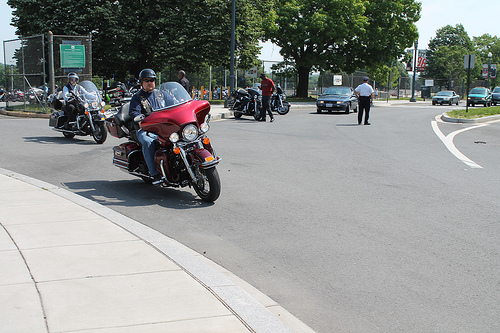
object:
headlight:
[181, 124, 199, 141]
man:
[61, 69, 98, 128]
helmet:
[139, 67, 158, 82]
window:
[143, 81, 193, 110]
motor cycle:
[101, 81, 231, 210]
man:
[125, 64, 185, 184]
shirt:
[127, 89, 185, 126]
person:
[354, 76, 374, 126]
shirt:
[354, 83, 375, 98]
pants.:
[259, 95, 275, 120]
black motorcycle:
[42, 79, 110, 145]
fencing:
[2, 28, 98, 113]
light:
[198, 122, 212, 134]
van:
[465, 84, 492, 108]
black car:
[312, 84, 362, 116]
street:
[0, 97, 499, 332]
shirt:
[258, 77, 276, 96]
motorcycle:
[223, 87, 269, 121]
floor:
[270, 128, 488, 271]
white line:
[429, 120, 445, 141]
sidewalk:
[3, 162, 311, 329]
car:
[430, 89, 462, 106]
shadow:
[57, 154, 216, 216]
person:
[127, 65, 161, 185]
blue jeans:
[135, 126, 160, 177]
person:
[257, 72, 277, 124]